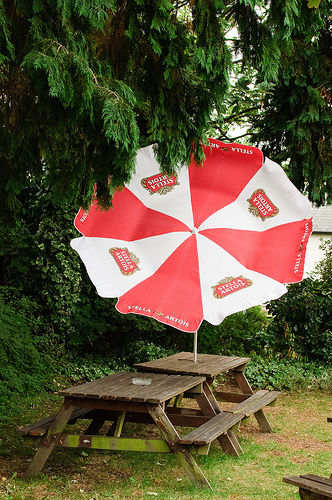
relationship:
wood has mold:
[53, 432, 173, 455] [72, 438, 167, 451]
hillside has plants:
[2, 260, 166, 378] [0, 251, 182, 395]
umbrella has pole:
[69, 136, 314, 363] [191, 324, 200, 363]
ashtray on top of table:
[130, 376, 153, 388] [19, 372, 240, 495]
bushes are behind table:
[71, 279, 331, 367] [134, 338, 283, 433]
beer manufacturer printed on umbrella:
[245, 189, 280, 222] [69, 136, 314, 363]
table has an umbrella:
[134, 338, 283, 433] [69, 136, 314, 363]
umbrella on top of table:
[69, 136, 314, 363] [134, 338, 283, 433]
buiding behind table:
[191, 8, 331, 290] [134, 338, 283, 433]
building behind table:
[191, 8, 331, 290] [134, 338, 283, 433]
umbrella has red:
[69, 136, 314, 363] [184, 138, 263, 230]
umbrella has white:
[69, 136, 314, 363] [194, 233, 291, 327]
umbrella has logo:
[69, 136, 314, 363] [206, 273, 255, 301]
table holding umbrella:
[134, 338, 283, 433] [69, 136, 314, 363]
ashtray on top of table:
[130, 376, 153, 388] [19, 375, 243, 476]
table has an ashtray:
[19, 375, 243, 476] [130, 376, 153, 388]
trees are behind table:
[0, 0, 330, 240] [134, 338, 283, 433]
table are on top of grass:
[19, 372, 240, 495] [2, 388, 329, 500]